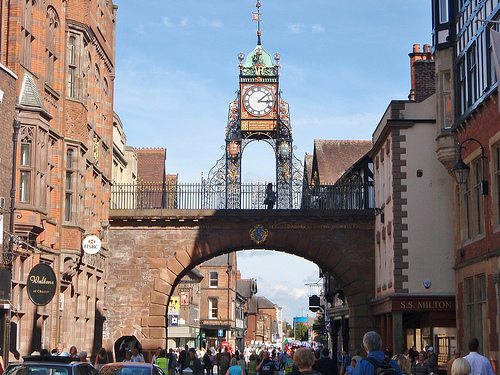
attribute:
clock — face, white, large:
[245, 80, 275, 124]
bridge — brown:
[110, 176, 369, 250]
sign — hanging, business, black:
[26, 264, 60, 309]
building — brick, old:
[7, 6, 113, 348]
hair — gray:
[360, 329, 382, 351]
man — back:
[469, 336, 494, 375]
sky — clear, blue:
[115, 2, 443, 174]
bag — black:
[374, 367, 406, 375]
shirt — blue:
[349, 353, 400, 375]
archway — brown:
[228, 104, 293, 210]